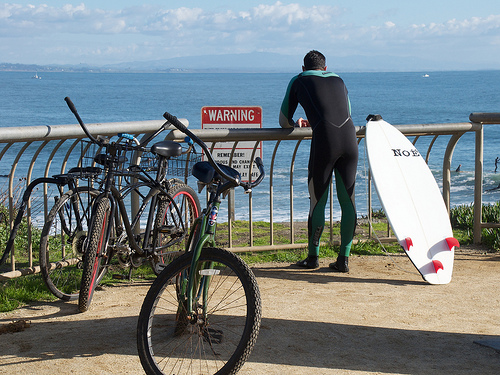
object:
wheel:
[89, 213, 113, 270]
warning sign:
[200, 103, 263, 185]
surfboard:
[367, 111, 455, 284]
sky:
[113, 14, 478, 47]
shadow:
[263, 250, 390, 297]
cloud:
[1, 2, 500, 39]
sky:
[1, 0, 498, 70]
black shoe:
[297, 256, 319, 268]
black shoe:
[327, 257, 348, 272]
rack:
[2, 110, 51, 285]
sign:
[195, 103, 270, 186]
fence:
[11, 115, 498, 267]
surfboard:
[362, 109, 467, 291]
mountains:
[105, 58, 245, 74]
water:
[1, 69, 498, 223]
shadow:
[1, 307, 498, 372]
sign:
[199, 105, 263, 185]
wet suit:
[276, 71, 360, 276]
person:
[494, 157, 499, 172]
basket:
[85, 141, 166, 179]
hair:
[302, 47, 324, 67]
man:
[279, 49, 359, 274]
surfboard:
[366, 111, 463, 286]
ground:
[0, 245, 499, 373]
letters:
[393, 149, 429, 157]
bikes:
[42, 146, 187, 296]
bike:
[139, 151, 260, 373]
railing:
[0, 119, 493, 268]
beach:
[0, 204, 495, 356]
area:
[452, 203, 476, 227]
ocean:
[2, 68, 499, 215]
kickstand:
[196, 317, 221, 357]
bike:
[69, 119, 207, 311]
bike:
[18, 142, 195, 282]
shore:
[1, 60, 477, 70]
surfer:
[491, 151, 499, 179]